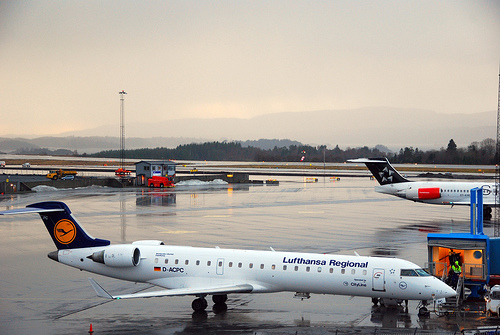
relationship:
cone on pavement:
[143, 150, 478, 306] [12, 181, 489, 329]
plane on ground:
[40, 200, 452, 317] [226, 192, 319, 258]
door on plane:
[371, 269, 387, 293] [0, 200, 459, 313]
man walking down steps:
[446, 258, 466, 290] [440, 263, 465, 315]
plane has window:
[343, 150, 498, 215] [255, 261, 269, 271]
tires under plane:
[180, 292, 230, 308] [0, 200, 459, 313]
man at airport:
[446, 258, 466, 290] [10, 26, 496, 316]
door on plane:
[367, 266, 392, 298] [24, 179, 465, 334]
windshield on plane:
[398, 268, 428, 278] [18, 230, 373, 310]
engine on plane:
[84, 242, 143, 267] [0, 200, 459, 313]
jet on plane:
[340, 138, 499, 210] [0, 200, 459, 313]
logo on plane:
[51, 215, 78, 251] [0, 200, 459, 313]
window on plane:
[399, 262, 431, 279] [40, 200, 452, 317]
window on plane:
[359, 266, 369, 276] [108, 220, 388, 327]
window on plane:
[339, 266, 347, 276] [0, 200, 459, 313]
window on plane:
[341, 267, 346, 274] [0, 200, 459, 313]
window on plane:
[304, 264, 313, 273] [0, 200, 459, 313]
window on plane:
[257, 262, 267, 268] [0, 200, 459, 313]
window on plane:
[193, 257, 202, 267] [0, 200, 459, 313]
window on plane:
[163, 257, 170, 264] [0, 200, 459, 313]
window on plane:
[304, 263, 311, 272] [0, 200, 459, 313]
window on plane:
[248, 262, 253, 268] [0, 200, 457, 312]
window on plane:
[236, 259, 245, 269] [0, 200, 459, 313]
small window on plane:
[293, 265, 299, 272] [0, 200, 459, 313]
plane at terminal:
[0, 200, 459, 313] [13, 173, 492, 333]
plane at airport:
[0, 200, 459, 313] [4, 150, 497, 333]